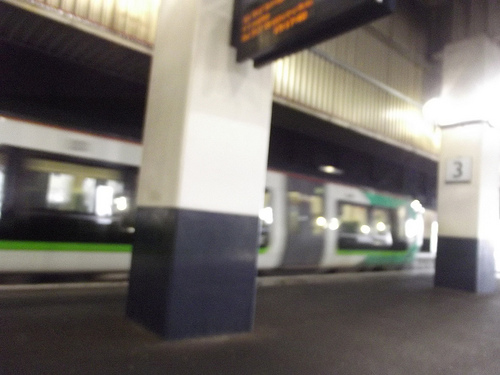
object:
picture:
[0, 0, 500, 375]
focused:
[326, 237, 428, 301]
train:
[0, 112, 435, 279]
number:
[449, 154, 467, 184]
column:
[161, 71, 270, 216]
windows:
[21, 158, 134, 228]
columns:
[122, 5, 498, 340]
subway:
[0, 116, 442, 283]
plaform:
[256, 270, 444, 375]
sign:
[226, 0, 328, 56]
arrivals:
[247, 12, 311, 30]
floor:
[251, 277, 500, 374]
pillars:
[143, 68, 498, 172]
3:
[450, 156, 464, 179]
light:
[308, 212, 390, 236]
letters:
[237, 0, 301, 33]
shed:
[321, 35, 419, 118]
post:
[123, 0, 257, 342]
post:
[436, 0, 500, 295]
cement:
[272, 277, 430, 371]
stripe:
[1, 231, 140, 257]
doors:
[283, 175, 331, 269]